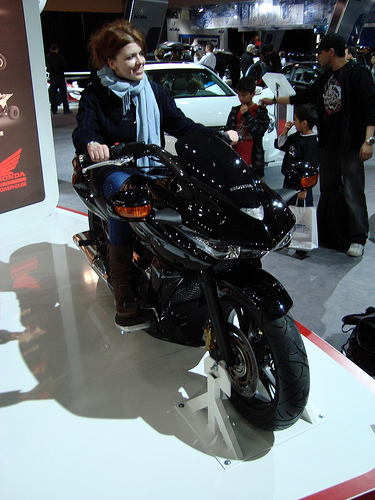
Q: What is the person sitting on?
A: A motorcycle.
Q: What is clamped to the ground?
A: The motorcycle.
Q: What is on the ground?
A: A shadow.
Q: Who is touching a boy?
A: A man.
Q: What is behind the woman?
A: A white car.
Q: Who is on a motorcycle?
A: A woman.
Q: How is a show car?
A: White.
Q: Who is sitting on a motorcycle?
A: Young lady.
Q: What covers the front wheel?
A: Rubber tread.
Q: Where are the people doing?
A: Attending a car and motorcycle show.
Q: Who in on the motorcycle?
A: A woman.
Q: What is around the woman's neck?
A: A blue scarf.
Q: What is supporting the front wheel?
A: A white frame.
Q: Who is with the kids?
A: The man in the black t-shirt,.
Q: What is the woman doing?
A: Sitting on the motorcycle.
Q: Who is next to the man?
A: Two kids.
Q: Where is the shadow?
A: On the platform.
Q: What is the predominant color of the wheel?
A: Black.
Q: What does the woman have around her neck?
A: Scarf.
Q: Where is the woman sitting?
A: Motorcycle.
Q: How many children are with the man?
A: 2.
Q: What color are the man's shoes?
A: White.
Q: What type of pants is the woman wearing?
A: Jeans.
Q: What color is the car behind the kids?
A: White.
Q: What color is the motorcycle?
A: Black.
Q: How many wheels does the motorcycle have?
A: 2.